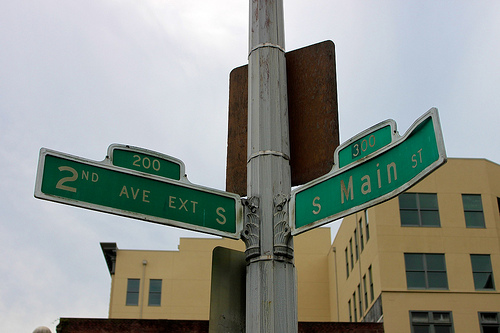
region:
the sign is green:
[284, 88, 486, 235]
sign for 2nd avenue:
[32, 140, 242, 243]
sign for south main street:
[288, 111, 444, 228]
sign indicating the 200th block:
[104, 137, 186, 185]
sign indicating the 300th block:
[338, 121, 396, 156]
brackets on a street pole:
[241, 192, 292, 262]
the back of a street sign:
[217, 31, 343, 193]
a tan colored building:
[53, 145, 498, 331]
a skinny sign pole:
[242, 1, 307, 331]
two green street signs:
[24, 105, 452, 242]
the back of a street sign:
[203, 237, 255, 331]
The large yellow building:
[95, 152, 496, 327]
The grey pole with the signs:
[240, 0, 305, 330]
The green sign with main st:
[280, 115, 450, 230]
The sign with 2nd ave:
[30, 136, 242, 246]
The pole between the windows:
[135, 256, 146, 326]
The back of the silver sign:
[202, 243, 249, 331]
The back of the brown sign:
[216, 39, 344, 194]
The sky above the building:
[0, 1, 498, 328]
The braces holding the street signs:
[241, 189, 296, 259]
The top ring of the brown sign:
[237, 40, 289, 59]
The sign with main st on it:
[288, 101, 458, 233]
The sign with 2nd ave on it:
[31, 128, 245, 250]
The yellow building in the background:
[98, 153, 498, 331]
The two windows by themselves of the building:
[120, 273, 169, 315]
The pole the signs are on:
[231, 0, 308, 331]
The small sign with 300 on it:
[334, 118, 394, 165]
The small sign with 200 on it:
[107, 140, 190, 182]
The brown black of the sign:
[217, 35, 342, 197]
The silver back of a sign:
[202, 243, 251, 331]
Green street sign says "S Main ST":
[284, 131, 454, 240]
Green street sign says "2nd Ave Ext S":
[20, 145, 247, 242]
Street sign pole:
[225, 76, 308, 328]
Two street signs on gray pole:
[21, 87, 459, 271]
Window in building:
[396, 226, 499, 328]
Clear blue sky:
[8, 2, 218, 139]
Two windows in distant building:
[88, 231, 181, 315]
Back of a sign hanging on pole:
[291, 58, 338, 148]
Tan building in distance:
[82, 231, 337, 329]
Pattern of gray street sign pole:
[251, 264, 293, 327]